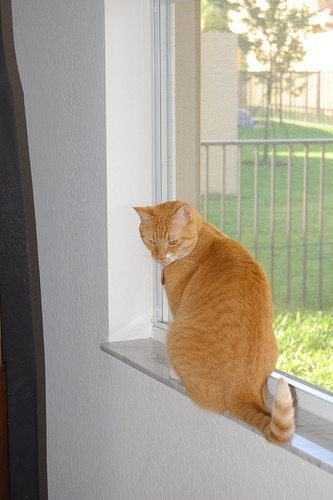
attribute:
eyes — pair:
[125, 216, 191, 250]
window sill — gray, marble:
[139, 349, 236, 417]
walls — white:
[55, 358, 209, 499]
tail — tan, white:
[267, 377, 303, 442]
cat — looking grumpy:
[127, 190, 303, 447]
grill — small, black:
[236, 106, 260, 141]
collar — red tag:
[158, 267, 167, 286]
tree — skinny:
[224, 0, 295, 167]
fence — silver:
[187, 149, 315, 251]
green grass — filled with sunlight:
[277, 311, 331, 371]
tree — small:
[238, 9, 311, 159]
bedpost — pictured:
[4, 356, 40, 466]